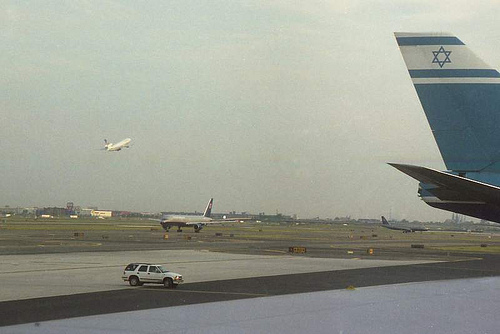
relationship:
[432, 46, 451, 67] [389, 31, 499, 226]
star on plane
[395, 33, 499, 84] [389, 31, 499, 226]
white on plane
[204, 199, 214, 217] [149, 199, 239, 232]
tail on plane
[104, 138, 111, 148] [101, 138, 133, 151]
tail on plane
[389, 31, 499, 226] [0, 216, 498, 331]
plane on ground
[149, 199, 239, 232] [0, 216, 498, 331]
plane on ground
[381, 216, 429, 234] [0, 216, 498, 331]
plane on ground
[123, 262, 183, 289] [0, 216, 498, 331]
car on ground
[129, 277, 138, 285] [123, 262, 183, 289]
wheel of car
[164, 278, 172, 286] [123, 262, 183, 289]
wheel of car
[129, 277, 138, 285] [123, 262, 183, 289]
wheel on car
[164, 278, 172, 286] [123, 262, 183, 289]
wheel on car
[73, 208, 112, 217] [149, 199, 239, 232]
building behind plane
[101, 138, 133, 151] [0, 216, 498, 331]
plane above ground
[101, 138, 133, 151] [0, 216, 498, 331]
plane flying above ground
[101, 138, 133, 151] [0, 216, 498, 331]
plane leaving ground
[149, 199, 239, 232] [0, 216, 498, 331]
plane waiting ground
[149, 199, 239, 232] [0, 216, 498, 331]
plane sitting on ground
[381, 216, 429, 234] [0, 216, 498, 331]
plane sitting on ground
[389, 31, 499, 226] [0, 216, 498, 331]
plane sitting on ground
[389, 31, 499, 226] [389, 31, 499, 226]
tail on plane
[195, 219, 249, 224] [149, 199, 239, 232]
wing on plane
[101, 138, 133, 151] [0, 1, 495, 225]
plane in sky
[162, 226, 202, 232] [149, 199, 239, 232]
wheel on plane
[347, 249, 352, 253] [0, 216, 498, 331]
object on ground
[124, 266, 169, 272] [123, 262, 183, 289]
windows on car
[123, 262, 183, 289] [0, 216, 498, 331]
car in ground